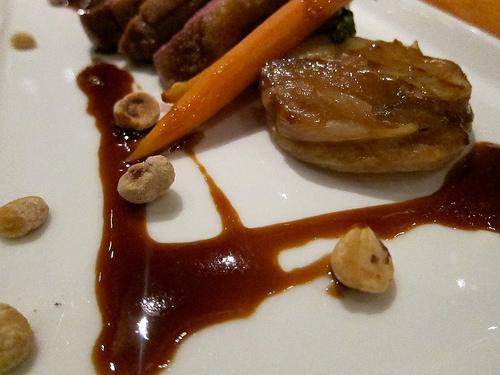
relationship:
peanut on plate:
[117, 153, 176, 204] [1, 0, 499, 373]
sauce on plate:
[76, 57, 498, 373] [1, 0, 499, 373]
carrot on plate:
[123, 0, 353, 164] [1, 0, 499, 373]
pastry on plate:
[259, 35, 476, 174] [1, 0, 499, 373]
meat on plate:
[152, 0, 292, 91] [1, 0, 499, 373]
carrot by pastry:
[123, 0, 353, 164] [259, 35, 476, 174]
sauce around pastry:
[76, 57, 498, 373] [259, 35, 476, 174]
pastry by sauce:
[259, 35, 476, 174] [76, 57, 498, 373]